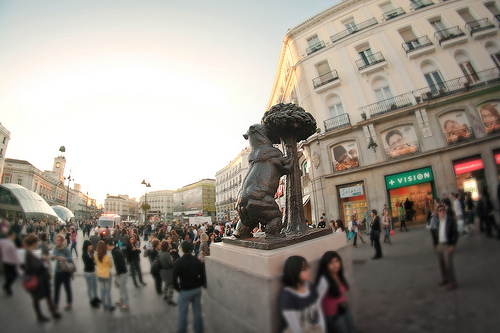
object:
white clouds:
[32, 127, 106, 183]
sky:
[3, 0, 282, 160]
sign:
[385, 166, 433, 190]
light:
[382, 165, 433, 190]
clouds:
[0, 68, 55, 118]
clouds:
[64, 45, 108, 89]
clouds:
[231, 47, 277, 76]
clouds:
[142, 140, 178, 185]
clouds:
[193, 54, 233, 94]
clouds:
[135, 52, 179, 101]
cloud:
[4, 1, 125, 51]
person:
[170, 241, 207, 331]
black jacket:
[173, 254, 207, 291]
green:
[383, 166, 432, 190]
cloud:
[156, 0, 281, 49]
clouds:
[205, 91, 258, 168]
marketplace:
[276, 154, 493, 315]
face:
[334, 145, 353, 166]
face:
[385, 135, 406, 150]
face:
[444, 120, 461, 135]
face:
[481, 110, 497, 126]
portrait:
[329, 139, 361, 172]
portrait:
[379, 122, 422, 161]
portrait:
[437, 109, 475, 144]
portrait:
[476, 100, 500, 134]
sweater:
[172, 253, 208, 291]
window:
[374, 85, 397, 111]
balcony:
[359, 91, 412, 117]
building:
[259, 0, 497, 225]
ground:
[0, 212, 500, 332]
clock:
[56, 162, 61, 168]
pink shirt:
[320, 277, 349, 317]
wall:
[265, 230, 354, 332]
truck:
[90, 213, 122, 236]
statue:
[222, 102, 333, 250]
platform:
[199, 227, 354, 331]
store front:
[383, 164, 440, 229]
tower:
[43, 146, 67, 179]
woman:
[278, 255, 326, 330]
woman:
[312, 250, 352, 332]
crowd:
[7, 206, 200, 302]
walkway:
[11, 216, 495, 320]